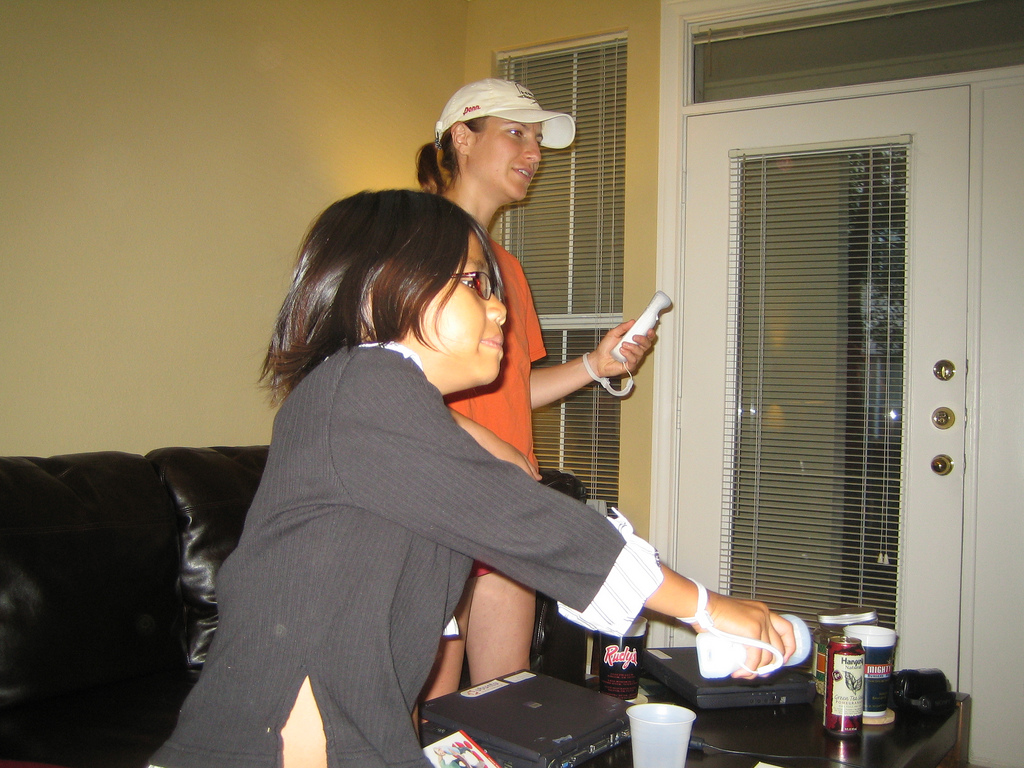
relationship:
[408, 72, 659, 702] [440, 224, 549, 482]
woman wearing woman shirt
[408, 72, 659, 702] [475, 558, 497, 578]
woman wearing shorts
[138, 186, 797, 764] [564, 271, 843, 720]
woman playing wii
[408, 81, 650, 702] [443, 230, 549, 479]
woman dressed in shirt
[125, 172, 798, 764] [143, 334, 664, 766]
woman dressed in woman shirt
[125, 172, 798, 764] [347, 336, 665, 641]
woman dressed in shirt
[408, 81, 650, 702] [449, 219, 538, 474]
woman wearing shirt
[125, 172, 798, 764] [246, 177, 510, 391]
woman has hair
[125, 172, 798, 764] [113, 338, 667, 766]
woman has shirt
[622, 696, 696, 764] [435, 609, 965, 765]
cup on table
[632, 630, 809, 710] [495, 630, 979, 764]
laptop on table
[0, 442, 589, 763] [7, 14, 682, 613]
sofa next to wall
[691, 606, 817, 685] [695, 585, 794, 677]
wii in girls hand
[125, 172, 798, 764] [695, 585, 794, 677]
woman has girls hand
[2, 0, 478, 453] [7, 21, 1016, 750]
wall attached to building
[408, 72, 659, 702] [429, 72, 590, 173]
woman in hat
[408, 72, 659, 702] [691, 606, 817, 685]
woman with wii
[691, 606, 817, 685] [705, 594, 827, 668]
wii for wii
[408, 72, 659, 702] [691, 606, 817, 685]
woman using wii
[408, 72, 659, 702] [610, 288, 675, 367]
woman using wii